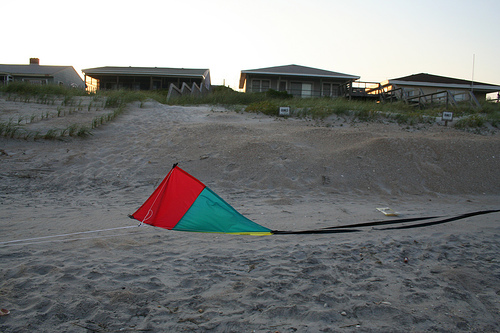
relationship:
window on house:
[278, 80, 286, 91] [250, 40, 356, 153]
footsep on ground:
[50, 299, 104, 329] [7, 255, 496, 328]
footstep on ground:
[294, 276, 351, 311] [7, 94, 495, 331]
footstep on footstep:
[370, 295, 431, 328] [26, 280, 96, 306]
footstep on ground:
[212, 266, 271, 302] [56, 130, 458, 331]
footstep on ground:
[110, 275, 163, 311] [56, 130, 458, 331]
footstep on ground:
[310, 243, 360, 269] [56, 130, 458, 331]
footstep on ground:
[26, 280, 96, 306] [56, 130, 458, 331]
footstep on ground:
[114, 270, 156, 280] [43, 111, 495, 329]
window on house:
[248, 75, 261, 97] [232, 50, 366, 110]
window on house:
[329, 61, 356, 102] [250, 52, 425, 144]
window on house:
[140, 79, 147, 88] [80, 64, 210, 95]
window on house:
[288, 84, 315, 99] [225, 54, 371, 104]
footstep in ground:
[21, 259, 71, 283] [7, 94, 495, 331]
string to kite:
[7, 204, 155, 263] [117, 147, 272, 251]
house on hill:
[0, 57, 87, 97] [1, 87, 498, 189]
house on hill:
[82, 65, 210, 102] [1, 87, 498, 189]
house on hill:
[237, 62, 361, 102] [1, 87, 498, 189]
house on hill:
[365, 70, 499, 112] [1, 87, 498, 189]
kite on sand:
[125, 159, 498, 237] [3, 102, 492, 331]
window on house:
[272, 81, 288, 91] [228, 54, 365, 135]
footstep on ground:
[343, 302, 401, 322] [29, 236, 494, 328]